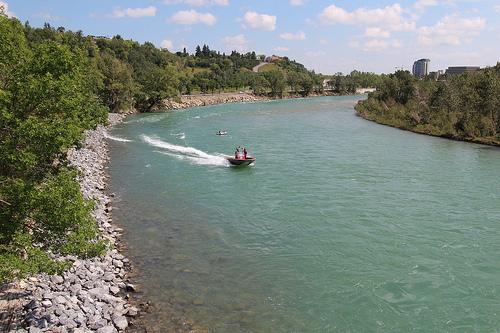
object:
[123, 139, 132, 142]
waves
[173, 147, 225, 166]
boat wake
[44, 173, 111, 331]
riverbank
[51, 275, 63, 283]
rocks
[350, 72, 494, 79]
horizon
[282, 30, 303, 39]
clouds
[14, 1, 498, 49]
sky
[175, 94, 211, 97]
roadway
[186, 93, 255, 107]
ridge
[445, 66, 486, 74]
building top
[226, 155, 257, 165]
speedboat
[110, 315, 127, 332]
rocks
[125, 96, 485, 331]
river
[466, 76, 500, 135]
trees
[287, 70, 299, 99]
trees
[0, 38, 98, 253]
trees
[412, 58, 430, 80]
buildings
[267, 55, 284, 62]
buildings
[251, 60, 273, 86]
hill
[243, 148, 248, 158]
people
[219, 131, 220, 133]
people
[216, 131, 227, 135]
mini-boat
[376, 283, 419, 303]
whirlpool